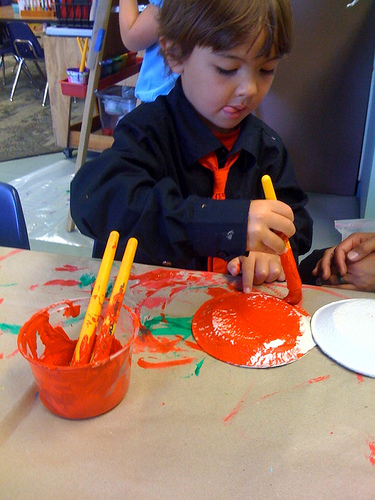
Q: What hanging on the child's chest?
A: Tie.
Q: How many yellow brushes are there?
A: 3.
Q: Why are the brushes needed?
A: To paint.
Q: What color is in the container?
A: Orange.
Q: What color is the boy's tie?
A: Orange.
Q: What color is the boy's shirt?
A: Blue.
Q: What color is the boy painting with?
A: Orange.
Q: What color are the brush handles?
A: Yellow.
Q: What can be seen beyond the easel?
A: Supply cart.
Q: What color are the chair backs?
A: Blue.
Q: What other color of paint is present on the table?
A: Green.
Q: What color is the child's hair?
A: Brown.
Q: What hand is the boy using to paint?
A: Right.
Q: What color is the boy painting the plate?
A: Orange.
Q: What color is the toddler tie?
A: Orange.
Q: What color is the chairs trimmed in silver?
A: Blue.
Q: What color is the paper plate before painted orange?
A: White.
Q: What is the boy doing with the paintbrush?
A: Painting.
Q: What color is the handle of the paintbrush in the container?
A: Yellow.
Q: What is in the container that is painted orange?
A: Paint brushes.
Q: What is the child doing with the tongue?
A: Sticking it out.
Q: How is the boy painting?
A: With a brush.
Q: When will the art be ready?
A: When the paint dries.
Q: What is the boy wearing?
A: A cub scout uniform.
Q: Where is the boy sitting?
A: At a table.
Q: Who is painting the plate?
A: A young boy.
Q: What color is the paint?
A: Orange.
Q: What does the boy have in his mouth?
A: His tongue.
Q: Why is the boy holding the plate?
A: So he can paint.